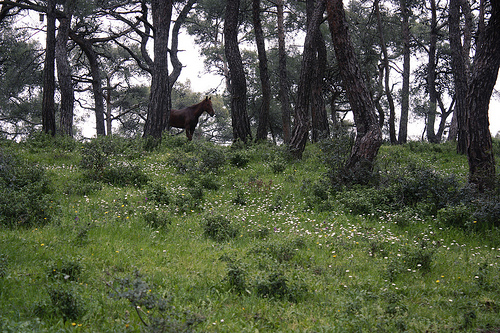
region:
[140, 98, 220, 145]
A big brown horse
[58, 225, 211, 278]
Thick green grass.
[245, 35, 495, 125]
Several trees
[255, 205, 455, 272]
Weeds are in the grass.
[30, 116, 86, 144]
Two tree trunks behind the brush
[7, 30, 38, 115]
Branches are on trees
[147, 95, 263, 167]
A horse in the woods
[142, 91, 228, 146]
A horse partially behind a tree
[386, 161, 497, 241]
bushes are by a tree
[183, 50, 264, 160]
A horse in front of a grey sky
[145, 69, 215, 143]
horse standing by a tree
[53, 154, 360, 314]
grassy area with wildflowers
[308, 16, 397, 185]
tree with curved trunk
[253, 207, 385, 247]
small white flowers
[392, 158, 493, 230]
bushes with green leaves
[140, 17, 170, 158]
the tree in front of the horse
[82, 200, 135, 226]
some small yellow flowers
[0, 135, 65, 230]
a large green bush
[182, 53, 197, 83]
the sky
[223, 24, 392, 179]
a group of trees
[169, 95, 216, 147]
a brown horse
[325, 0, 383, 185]
a crooked tree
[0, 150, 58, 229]
a green bush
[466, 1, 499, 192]
a curved tree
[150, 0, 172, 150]
a tree with gray and black bark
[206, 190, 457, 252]
a group of wildflowers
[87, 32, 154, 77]
branches on a tree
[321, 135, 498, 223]
brush under a tree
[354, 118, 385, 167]
a knot on a tree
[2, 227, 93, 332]
a patch of grass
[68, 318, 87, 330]
small yellow flowers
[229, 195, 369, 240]
small white flowers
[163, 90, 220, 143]
brown horse in the distance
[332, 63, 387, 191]
a curving tree trunk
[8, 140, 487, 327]
green grass growing among trees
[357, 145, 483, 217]
patch of dark green brush between two trees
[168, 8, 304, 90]
white-looking sky between trees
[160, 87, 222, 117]
the horse is looking straight ahead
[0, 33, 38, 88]
dark green leaves on trees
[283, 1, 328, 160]
tree leaning to the right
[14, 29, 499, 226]
Forrest with horse in it.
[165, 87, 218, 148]
Brown horse, standing by tree.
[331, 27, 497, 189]
Curving, misshapen, tree trunks.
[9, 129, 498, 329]
Grassy slope. leading away from trees.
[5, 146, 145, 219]
dark green bushes amidst lighter colored grass.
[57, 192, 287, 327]
Shorter, lighter grass, between bushes.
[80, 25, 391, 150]
White light, shining through trees.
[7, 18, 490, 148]
Green treetops, visible through network of tree trunks.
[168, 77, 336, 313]
Horse on top of green slope.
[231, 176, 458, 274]
Small, white flowers on green slope.